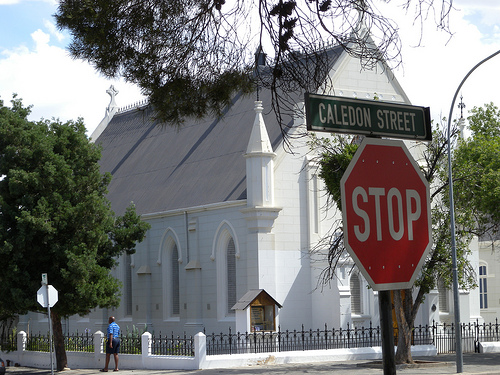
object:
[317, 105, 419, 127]
caledon street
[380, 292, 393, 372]
pole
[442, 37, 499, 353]
lampole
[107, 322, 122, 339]
blue t-shirt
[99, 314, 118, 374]
man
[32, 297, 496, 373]
fence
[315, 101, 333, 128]
white letter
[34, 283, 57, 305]
back side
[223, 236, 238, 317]
window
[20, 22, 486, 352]
building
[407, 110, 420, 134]
white letter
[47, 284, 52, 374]
pole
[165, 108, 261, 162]
floor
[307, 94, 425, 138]
sign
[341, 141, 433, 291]
sign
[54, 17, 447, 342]
church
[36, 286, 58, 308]
sign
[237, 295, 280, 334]
board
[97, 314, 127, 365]
pedestrian